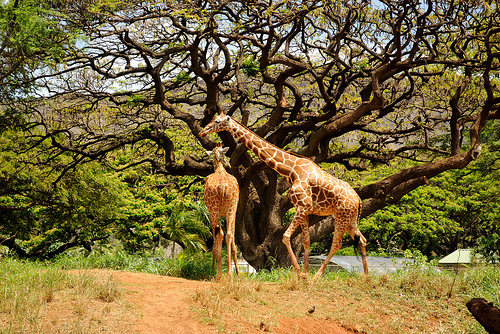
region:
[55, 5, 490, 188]
large tree with many curvy branches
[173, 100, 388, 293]
two giraffes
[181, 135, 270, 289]
baby giraffe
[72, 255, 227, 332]
red dirt path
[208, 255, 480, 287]
fence surrounding the giraffe enclosure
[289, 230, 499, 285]
buildings outside the giraffe enclosure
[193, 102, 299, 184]
long giraffe neck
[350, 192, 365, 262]
long, brown giraffe tail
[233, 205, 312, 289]
thick, many branched tree trunk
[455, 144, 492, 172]
scarred wound on tree branch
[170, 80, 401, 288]
Two giraffes standing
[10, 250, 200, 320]
Ground with dirt and grass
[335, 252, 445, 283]
Roof of a building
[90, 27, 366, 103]
Limbs on a tree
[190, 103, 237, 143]
Head of a giraffe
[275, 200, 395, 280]
Legs of a giraffe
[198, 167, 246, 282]
Back of a giraffe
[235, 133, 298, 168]
Neck of a giraffe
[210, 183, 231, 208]
Tail of a giraffe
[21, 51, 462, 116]
Mountains in the distance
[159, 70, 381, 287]
Giraffes by a tree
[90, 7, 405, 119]
Tree with very little leaves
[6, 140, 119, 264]
A tree with a lot of leaves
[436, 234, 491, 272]
The roof of a building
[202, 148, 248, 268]
The view of a giraffe from behind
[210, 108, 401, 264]
The view of a giraffe from the side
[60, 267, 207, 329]
Dirt with very little grass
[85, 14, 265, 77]
The sky through the tree limbs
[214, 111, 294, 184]
A long giraffe neck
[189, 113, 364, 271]
Two giraffes standing together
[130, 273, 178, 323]
red clay on the dirt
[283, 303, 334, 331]
small brown spot on the ground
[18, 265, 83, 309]
cluster of green grass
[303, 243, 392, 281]
gray edge of the house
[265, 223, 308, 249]
large white knee on giraffe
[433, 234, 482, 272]
yellow roof on building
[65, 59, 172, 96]
white skies overhead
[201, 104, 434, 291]
large brown and white giraffe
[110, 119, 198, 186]
solid black branches of trees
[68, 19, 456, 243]
large green tree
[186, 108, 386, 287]
giraffe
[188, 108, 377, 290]
two giraffe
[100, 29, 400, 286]
two giraffe by a tree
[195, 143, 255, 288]
the younger giraffe has it's back to the camera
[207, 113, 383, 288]
the rightmost giraffe is walking to the left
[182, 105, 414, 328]
the giraffes are on a small hill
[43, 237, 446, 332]
the hill is mostly dirt with some grass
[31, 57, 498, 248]
hills are in the background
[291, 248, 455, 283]
a metal building is down the hill from the animals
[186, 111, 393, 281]
two animals stand together